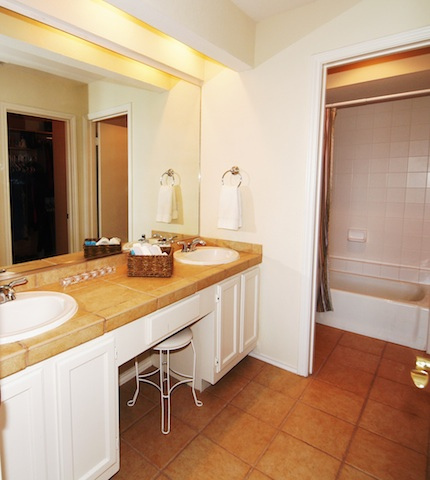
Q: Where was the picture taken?
A: It was taken at the bathroom.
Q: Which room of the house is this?
A: It is a bathroom.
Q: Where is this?
A: This is at the bathroom.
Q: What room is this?
A: It is a bathroom.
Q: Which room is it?
A: It is a bathroom.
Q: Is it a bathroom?
A: Yes, it is a bathroom.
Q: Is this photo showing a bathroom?
A: Yes, it is showing a bathroom.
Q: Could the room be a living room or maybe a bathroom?
A: It is a bathroom.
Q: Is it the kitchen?
A: No, it is the bathroom.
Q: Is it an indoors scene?
A: Yes, it is indoors.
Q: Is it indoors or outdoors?
A: It is indoors.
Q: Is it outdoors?
A: No, it is indoors.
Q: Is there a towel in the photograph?
A: Yes, there is a towel.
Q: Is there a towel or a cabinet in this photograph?
A: Yes, there is a towel.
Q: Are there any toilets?
A: No, there are no toilets.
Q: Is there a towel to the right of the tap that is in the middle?
A: No, the towel is to the left of the tap.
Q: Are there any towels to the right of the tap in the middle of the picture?
A: No, the towel is to the left of the tap.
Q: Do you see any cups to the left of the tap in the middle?
A: No, there is a towel to the left of the tap.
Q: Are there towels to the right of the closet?
A: Yes, there is a towel to the right of the closet.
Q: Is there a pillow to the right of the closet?
A: No, there is a towel to the right of the closet.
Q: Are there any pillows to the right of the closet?
A: No, there is a towel to the right of the closet.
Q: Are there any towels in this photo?
A: Yes, there is a towel.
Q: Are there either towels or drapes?
A: Yes, there is a towel.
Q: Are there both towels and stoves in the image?
A: No, there is a towel but no stoves.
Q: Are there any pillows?
A: No, there are no pillows.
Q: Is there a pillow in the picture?
A: No, there are no pillows.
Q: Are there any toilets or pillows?
A: No, there are no pillows or toilets.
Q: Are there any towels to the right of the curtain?
A: No, the towel is to the left of the curtain.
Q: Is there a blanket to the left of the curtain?
A: No, there is a towel to the left of the curtain.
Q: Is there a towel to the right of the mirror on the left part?
A: Yes, there is a towel to the right of the mirror.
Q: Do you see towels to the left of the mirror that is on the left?
A: No, the towel is to the right of the mirror.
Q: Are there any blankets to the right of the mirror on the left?
A: No, there is a towel to the right of the mirror.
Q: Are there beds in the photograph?
A: No, there are no beds.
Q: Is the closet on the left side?
A: Yes, the closet is on the left of the image.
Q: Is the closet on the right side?
A: No, the closet is on the left of the image.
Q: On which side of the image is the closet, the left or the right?
A: The closet is on the left of the image.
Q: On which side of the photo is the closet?
A: The closet is on the left of the image.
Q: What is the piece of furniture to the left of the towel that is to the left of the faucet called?
A: The piece of furniture is a closet.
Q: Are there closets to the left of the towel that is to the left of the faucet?
A: Yes, there is a closet to the left of the towel.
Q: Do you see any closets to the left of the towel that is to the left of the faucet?
A: Yes, there is a closet to the left of the towel.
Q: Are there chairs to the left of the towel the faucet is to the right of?
A: No, there is a closet to the left of the towel.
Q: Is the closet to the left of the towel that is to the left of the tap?
A: Yes, the closet is to the left of the towel.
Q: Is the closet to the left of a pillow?
A: No, the closet is to the left of the towel.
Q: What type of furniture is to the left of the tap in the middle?
A: The piece of furniture is a closet.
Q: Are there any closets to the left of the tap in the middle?
A: Yes, there is a closet to the left of the faucet.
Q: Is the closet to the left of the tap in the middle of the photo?
A: Yes, the closet is to the left of the tap.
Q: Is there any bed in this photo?
A: No, there are no beds.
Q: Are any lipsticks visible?
A: No, there are no lipsticks.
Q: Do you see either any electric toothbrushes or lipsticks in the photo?
A: No, there are no lipsticks or electric toothbrushes.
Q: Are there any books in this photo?
A: No, there are no books.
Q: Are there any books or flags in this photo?
A: No, there are no books or flags.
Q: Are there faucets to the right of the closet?
A: Yes, there is a faucet to the right of the closet.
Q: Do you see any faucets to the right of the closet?
A: Yes, there is a faucet to the right of the closet.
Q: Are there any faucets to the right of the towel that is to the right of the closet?
A: Yes, there is a faucet to the right of the towel.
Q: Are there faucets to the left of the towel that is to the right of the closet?
A: No, the faucet is to the right of the towel.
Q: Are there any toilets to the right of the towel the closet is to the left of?
A: No, there is a faucet to the right of the towel.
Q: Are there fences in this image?
A: No, there are no fences.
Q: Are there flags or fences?
A: No, there are no fences or flags.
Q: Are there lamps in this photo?
A: No, there are no lamps.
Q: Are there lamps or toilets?
A: No, there are no lamps or toilets.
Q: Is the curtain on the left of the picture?
A: No, the curtain is on the right of the image.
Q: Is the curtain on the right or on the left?
A: The curtain is on the right of the image.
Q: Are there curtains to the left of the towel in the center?
A: No, the curtain is to the right of the towel.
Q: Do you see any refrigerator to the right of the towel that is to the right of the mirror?
A: No, there is a curtain to the right of the towel.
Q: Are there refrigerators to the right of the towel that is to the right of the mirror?
A: No, there is a curtain to the right of the towel.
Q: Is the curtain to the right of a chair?
A: No, the curtain is to the right of the towel.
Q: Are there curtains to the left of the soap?
A: Yes, there is a curtain to the left of the soap.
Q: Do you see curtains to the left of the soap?
A: Yes, there is a curtain to the left of the soap.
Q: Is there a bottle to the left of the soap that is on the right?
A: No, there is a curtain to the left of the soap.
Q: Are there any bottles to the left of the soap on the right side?
A: No, there is a curtain to the left of the soap.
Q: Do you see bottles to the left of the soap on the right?
A: No, there is a curtain to the left of the soap.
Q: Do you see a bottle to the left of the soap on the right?
A: No, there is a curtain to the left of the soap.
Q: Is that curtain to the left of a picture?
A: No, the curtain is to the left of the soap.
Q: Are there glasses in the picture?
A: No, there are no glasses.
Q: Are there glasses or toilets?
A: No, there are no glasses or toilets.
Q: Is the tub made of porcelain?
A: Yes, the tub is made of porcelain.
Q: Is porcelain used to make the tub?
A: Yes, the tub is made of porcelain.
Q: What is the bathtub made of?
A: The bath tub is made of porcelain.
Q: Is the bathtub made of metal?
A: No, the bathtub is made of porcelain.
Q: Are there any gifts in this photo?
A: No, there are no gifts.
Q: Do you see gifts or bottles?
A: No, there are no gifts or bottles.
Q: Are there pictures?
A: No, there are no pictures.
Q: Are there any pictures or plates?
A: No, there are no pictures or plates.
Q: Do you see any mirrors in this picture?
A: Yes, there is a mirror.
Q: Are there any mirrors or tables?
A: Yes, there is a mirror.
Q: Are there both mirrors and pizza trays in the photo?
A: No, there is a mirror but no pizza trays.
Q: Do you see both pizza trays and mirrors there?
A: No, there is a mirror but no pizza trays.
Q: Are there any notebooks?
A: No, there are no notebooks.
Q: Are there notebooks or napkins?
A: No, there are no notebooks or napkins.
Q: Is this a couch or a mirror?
A: This is a mirror.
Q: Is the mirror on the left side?
A: Yes, the mirror is on the left of the image.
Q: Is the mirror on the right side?
A: No, the mirror is on the left of the image.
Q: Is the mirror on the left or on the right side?
A: The mirror is on the left of the image.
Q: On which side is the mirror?
A: The mirror is on the left of the image.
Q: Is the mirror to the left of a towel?
A: Yes, the mirror is to the left of a towel.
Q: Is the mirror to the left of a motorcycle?
A: No, the mirror is to the left of a towel.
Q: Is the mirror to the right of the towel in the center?
A: No, the mirror is to the left of the towel.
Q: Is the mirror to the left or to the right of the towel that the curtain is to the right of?
A: The mirror is to the left of the towel.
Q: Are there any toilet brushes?
A: No, there are no toilet brushes.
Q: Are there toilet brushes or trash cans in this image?
A: No, there are no toilet brushes or trash cans.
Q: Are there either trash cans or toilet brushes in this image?
A: No, there are no toilet brushes or trash cans.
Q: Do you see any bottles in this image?
A: No, there are no bottles.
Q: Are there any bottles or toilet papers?
A: No, there are no bottles or toilet papers.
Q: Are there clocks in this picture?
A: No, there are no clocks.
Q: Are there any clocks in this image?
A: No, there are no clocks.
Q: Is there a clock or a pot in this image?
A: No, there are no clocks or pots.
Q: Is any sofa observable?
A: No, there are no sofas.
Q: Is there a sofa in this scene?
A: No, there are no sofas.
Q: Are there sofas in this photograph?
A: No, there are no sofas.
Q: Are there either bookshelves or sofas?
A: No, there are no sofas or bookshelves.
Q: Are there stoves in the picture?
A: No, there are no stoves.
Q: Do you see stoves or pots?
A: No, there are no stoves or pots.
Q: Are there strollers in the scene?
A: No, there are no strollers.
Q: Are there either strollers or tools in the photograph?
A: No, there are no strollers or tools.